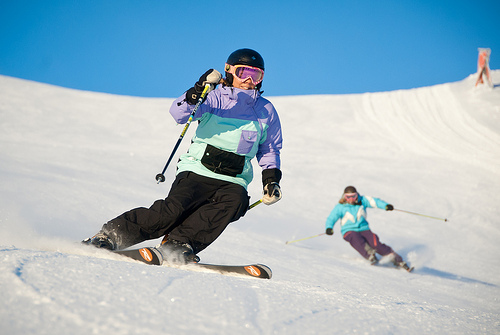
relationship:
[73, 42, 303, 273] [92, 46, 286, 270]
female suit has female suit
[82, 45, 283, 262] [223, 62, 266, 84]
female in goggles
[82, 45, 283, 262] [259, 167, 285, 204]
female wearing gloves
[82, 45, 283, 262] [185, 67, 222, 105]
female wearing gloves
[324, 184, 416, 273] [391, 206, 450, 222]
girl holding ski pole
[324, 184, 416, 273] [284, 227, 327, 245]
girl holding ski pole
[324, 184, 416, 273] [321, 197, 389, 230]
girl in jacket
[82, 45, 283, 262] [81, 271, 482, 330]
female in snow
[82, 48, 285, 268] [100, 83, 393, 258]
female wearing ski suits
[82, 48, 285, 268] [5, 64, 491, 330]
female skiing in snow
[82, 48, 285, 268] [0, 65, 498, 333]
female coming down mountain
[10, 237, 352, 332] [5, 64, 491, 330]
tracks in snow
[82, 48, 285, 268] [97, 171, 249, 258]
female wearing black pants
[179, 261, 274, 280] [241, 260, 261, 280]
skies with logo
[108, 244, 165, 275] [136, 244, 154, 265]
skies with logo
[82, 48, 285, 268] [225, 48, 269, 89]
female wearing helmet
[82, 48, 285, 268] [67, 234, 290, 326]
female on ski slope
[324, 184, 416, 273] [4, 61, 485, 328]
girl on ski slope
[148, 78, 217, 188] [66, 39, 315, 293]
pole in skier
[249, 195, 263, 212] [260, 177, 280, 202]
ski pole in hand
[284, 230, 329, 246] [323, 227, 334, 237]
ski pole in hand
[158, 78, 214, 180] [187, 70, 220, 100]
pole in hand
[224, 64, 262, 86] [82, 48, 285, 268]
glasses on female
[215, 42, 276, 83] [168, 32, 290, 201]
helmet on skier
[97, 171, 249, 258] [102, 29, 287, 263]
black pants in skier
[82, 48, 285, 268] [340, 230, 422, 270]
female wearing pants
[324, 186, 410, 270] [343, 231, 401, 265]
girl wearing pants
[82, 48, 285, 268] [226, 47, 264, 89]
female wearing helmet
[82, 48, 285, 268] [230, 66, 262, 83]
female has glasses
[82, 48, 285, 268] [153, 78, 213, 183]
female holding pole